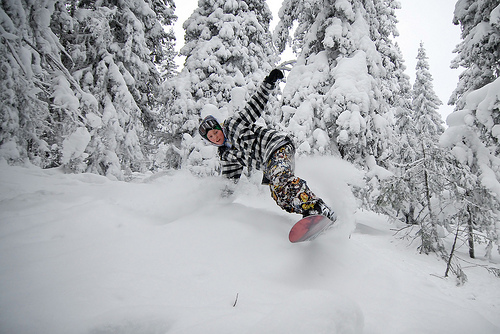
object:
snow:
[2, 154, 500, 333]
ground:
[0, 161, 500, 333]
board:
[289, 215, 336, 244]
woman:
[198, 66, 341, 221]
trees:
[265, 0, 419, 222]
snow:
[2, 1, 500, 333]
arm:
[224, 67, 286, 122]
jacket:
[218, 81, 292, 206]